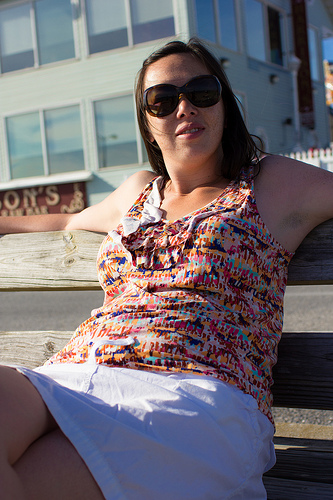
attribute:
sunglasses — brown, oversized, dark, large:
[140, 72, 225, 118]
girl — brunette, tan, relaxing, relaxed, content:
[1, 34, 332, 498]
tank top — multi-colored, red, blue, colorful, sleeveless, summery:
[41, 151, 298, 427]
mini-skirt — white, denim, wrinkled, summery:
[15, 360, 277, 500]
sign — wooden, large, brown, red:
[0, 180, 88, 216]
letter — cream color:
[3, 189, 19, 210]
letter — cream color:
[24, 188, 37, 209]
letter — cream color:
[45, 185, 59, 204]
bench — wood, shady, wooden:
[1, 218, 332, 500]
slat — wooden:
[0, 220, 332, 291]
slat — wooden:
[1, 330, 332, 408]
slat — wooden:
[263, 421, 332, 484]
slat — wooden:
[260, 475, 332, 500]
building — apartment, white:
[0, 0, 332, 206]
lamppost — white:
[284, 54, 304, 151]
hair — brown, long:
[134, 37, 265, 182]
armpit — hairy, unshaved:
[282, 209, 311, 229]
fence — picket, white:
[276, 147, 332, 171]